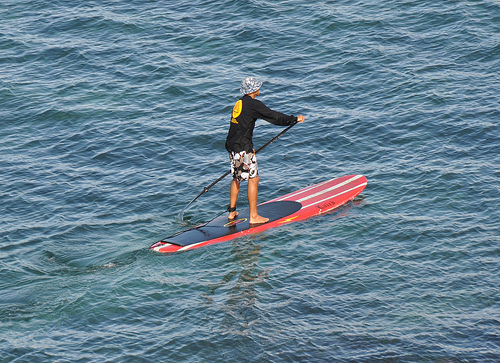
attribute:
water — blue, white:
[1, 1, 500, 363]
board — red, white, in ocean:
[150, 175, 368, 254]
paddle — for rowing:
[180, 118, 301, 211]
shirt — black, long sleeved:
[225, 96, 297, 152]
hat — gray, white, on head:
[240, 76, 262, 95]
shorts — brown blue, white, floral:
[230, 150, 259, 180]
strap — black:
[228, 207, 235, 212]